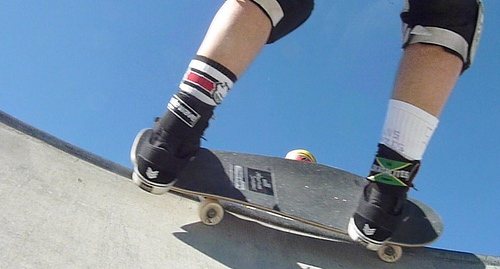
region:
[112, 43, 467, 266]
a person standing on a skateboard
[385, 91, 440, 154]
a person wearing a white sock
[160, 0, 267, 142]
the left leg of a person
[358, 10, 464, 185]
the right leg of a person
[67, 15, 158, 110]
blue cloudless sky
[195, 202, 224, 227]
the rear wheel of a skateboard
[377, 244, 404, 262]
the front wheel of a skateboard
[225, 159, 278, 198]
writing on the top of a skateboard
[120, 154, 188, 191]
shoe that is white and black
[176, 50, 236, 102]
a red, black, and white sock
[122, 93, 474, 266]
A person with skateboard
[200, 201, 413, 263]
Black color skateboard with wheels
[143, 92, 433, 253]
A person wearing pair of shoes and socks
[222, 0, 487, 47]
A person wearing knee cap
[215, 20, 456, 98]
Legs of the person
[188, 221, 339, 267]
Shadow of the skateboard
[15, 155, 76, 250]
grey color floor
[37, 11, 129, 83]
Blue color wall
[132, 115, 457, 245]
A person standing in the skateboard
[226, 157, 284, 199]
Some text written in the skateboard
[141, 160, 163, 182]
the logo on the shoe heel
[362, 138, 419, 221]
the brac eon the ankle oif the skateboarder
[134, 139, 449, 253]
the skateboarder rides the board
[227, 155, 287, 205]
the sticker on top of the board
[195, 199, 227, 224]
the wheel on the ramp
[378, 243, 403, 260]
the white wheel of the skateboard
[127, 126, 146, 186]
the white sole of the shoe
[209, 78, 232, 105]
the spitfire logo on the sock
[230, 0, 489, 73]
the kneepads on the skateboarders knees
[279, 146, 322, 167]
the helmet over the board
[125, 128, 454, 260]
a black skateboard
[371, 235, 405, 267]
front wheel of skateboard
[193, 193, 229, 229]
back wheel of skateboard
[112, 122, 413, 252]
black shoes with white soles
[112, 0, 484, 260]
legs on a skateboard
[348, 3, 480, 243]
right legs on a skateboard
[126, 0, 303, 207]
right legs on a skateboard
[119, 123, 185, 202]
white sole of shoe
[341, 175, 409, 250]
white sole of shoe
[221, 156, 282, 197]
a label on skateboard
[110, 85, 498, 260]
man skateboarding on ramp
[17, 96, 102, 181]
metal edge of concrete ramp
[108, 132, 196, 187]
black and white skater shoe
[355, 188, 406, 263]
black and white skater shoe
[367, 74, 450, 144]
tall white sock on skateboarder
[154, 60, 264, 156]
tall black and red and white sock on skateboarder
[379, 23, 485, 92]
knee pad on skater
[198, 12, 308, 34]
knee pad on skater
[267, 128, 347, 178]
object behind skateboard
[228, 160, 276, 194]
square sticker on skateboard